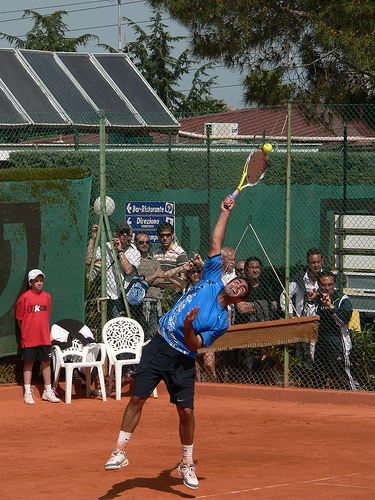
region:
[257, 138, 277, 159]
Racket hitting tennis ball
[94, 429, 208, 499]
Man jumping off ground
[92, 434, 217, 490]
Man wearing white shoes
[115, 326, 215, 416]
Man wearing black shorts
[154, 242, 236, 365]
Man wearing blue shirt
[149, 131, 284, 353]
Man hitting a tennis ball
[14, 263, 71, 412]
Boy watching tennis match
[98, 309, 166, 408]
White chair on a clay tennis court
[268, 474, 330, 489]
White line on a clay court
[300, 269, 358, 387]
Man standing behind a fence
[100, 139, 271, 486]
Tennis player hitting a tennis ball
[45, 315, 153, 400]
two white chairs made of plastic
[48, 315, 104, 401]
jacket draped over back of chair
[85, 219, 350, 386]
spectators watching a tennis match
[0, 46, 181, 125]
solar panels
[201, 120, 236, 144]
roof mounted air conditioner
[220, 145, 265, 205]
tennis racket with a yellow frame and blue handle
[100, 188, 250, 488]
man jumping and swinging to hit tennis ball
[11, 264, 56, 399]
boy in a red shirt and white hat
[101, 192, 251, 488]
tennis player wearing blue shirt and black shorts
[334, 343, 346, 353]
part of a fence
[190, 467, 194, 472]
part of a shoe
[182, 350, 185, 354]
part of a shirt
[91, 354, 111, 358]
part of a chair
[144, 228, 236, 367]
the shirt is blue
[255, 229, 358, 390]
men watching outside the fence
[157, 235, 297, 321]
men watching outside the fence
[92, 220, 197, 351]
men watching outside the fence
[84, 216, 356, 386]
People behind the fence watchin tennis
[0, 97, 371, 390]
Chain link fence between the court and the people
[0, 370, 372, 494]
Brown tennis court floor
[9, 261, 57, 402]
Young boy in red shirt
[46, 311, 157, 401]
Two patio chairs on the court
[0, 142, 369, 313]
Green building wall behind the people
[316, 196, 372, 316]
Window in the green wall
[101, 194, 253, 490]
Man on the court playing tennis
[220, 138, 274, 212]
Tennis racket hitting the ball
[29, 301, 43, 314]
White K on the boys red shirt